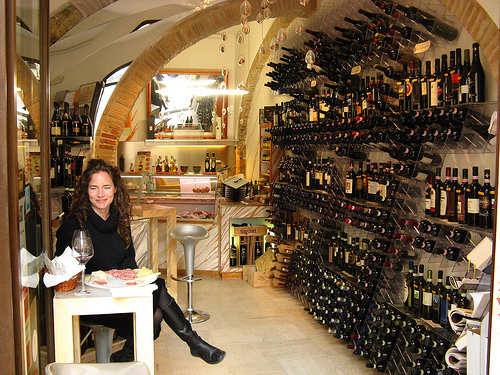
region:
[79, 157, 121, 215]
the head of the woman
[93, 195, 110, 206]
the mouth of the woman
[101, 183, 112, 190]
the eye of the woman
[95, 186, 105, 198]
the nose of the woman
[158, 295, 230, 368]
a black boot on the woman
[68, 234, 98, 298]
a wine glass on the table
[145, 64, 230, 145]
a window in the background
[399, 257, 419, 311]
a glass wine bottle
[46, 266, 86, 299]
a brown basket on the table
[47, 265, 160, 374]
a white table in front of the woman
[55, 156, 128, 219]
the woman is smiling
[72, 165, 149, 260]
the woman has dark curly hair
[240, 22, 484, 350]
the room has a wall full of wine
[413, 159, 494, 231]
wine bottles standing on a shelf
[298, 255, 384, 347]
wine bottles laying in the rack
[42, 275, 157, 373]
a white table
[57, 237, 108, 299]
an empty wine glass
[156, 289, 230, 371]
black knee high boots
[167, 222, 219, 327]
a silver stool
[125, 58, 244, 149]
a mirror on the wall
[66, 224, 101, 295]
pair of empty wine glasses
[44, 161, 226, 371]
woman wearing all black everything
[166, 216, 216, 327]
a silver designer stool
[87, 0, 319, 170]
a brick archway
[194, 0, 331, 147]
a set of glass crystal ornaments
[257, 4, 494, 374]
a very large array of wines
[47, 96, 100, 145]
a shelf of red wines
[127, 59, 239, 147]
a mirror reflecting a flash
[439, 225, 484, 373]
a shelf of informational material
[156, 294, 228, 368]
a black calf length boot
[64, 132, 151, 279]
woman in black shirt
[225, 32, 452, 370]
many wine bottles on wall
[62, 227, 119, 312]
wine glasses on white table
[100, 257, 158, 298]
plate of food on white table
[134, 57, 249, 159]
mirror on wall in photo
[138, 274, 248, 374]
woman wearing black knee-high boots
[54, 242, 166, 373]
white table in photograph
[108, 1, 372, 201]
arched doorway in photo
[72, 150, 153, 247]
woman with brown hair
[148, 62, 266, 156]
light reflected in mirror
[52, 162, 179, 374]
A woman in black sitting at a table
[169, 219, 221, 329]
A silver bar stool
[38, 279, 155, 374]
A white table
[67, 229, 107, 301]
Two wine glasses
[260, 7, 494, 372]
A wall full of wine bottles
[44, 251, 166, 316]
Food sitting on a white table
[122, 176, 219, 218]
A deli counter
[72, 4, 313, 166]
A brick arch way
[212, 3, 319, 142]
Hanging glass drops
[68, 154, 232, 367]
A woman wearing black boots